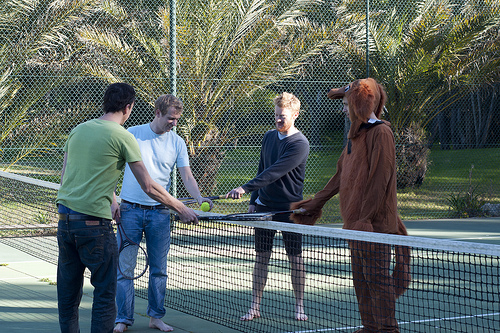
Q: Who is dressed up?
A: A dog.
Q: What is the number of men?
A: Four.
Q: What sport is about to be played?
A: Tennis.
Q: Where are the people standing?
A: On a tennis court.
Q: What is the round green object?
A: A tennis ball.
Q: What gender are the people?
A: Male.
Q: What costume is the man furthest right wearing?
A: A dog suit.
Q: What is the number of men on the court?
A: Four.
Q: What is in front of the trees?
A: A fence.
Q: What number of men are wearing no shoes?
A: Two.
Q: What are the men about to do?
A: Play tennis.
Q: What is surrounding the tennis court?
A: A fence.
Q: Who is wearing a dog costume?
A: The man on the right.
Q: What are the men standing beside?
A: A net.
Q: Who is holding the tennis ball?
A: The man in the light blue shirt.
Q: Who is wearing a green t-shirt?
A: The man on the left.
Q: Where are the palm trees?
A: Behind the tennis court.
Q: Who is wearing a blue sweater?
A: The second man from the left.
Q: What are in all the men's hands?
A: Tennis rackets.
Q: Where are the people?
A: On a tennis court.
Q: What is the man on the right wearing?
A: A dog costume.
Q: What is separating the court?
A: A net.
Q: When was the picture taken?
A: Daytime.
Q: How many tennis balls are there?
A: One.